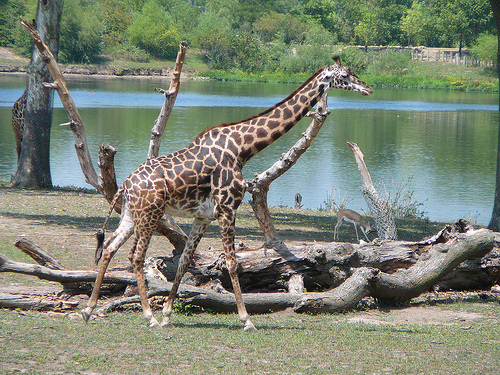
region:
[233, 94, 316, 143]
neck of the giraffe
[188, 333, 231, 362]
grass on the ground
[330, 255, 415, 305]
log on the ground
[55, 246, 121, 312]
back leg of the animal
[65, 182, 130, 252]
tail of the giraffe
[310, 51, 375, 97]
head of the giraffe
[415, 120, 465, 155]
water next to giraffes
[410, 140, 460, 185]
light and dark water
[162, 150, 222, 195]
brown spots on the animal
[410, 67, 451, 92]
grass in the distance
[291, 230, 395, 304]
logs on the ground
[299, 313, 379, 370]
grass on the ground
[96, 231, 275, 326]
legs of the giraffe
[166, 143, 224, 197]
brown spots on animal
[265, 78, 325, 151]
neck of the giraffe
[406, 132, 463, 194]
reflection in the water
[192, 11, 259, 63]
trees in the distance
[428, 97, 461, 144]
water next to giraffe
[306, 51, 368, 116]
head of the animal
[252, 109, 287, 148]
part of a neck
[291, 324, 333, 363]
part of a ground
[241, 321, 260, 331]
part of a hoof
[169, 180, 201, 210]
part of a tomach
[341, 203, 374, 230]
part of a deer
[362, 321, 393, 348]
part of a ground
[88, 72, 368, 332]
Giraffe walking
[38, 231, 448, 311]
Tree limbs laying on ground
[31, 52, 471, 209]
Lake surrounded by trees and shrubs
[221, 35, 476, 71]
Wooden bridge partially hidden behind shrubs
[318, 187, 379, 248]
Young animal bending down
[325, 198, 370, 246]
Fawn bending down eating grass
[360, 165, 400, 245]
Fencing around a tree limb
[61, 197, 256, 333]
Giraffe in mid-stride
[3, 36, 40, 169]
A giraffe partially hidden behind tree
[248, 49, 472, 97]
Yellow flowers on opposite side of lake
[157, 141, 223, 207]
brown and white animal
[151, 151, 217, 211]
brown spots on giraffe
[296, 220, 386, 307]
logs next to giraffe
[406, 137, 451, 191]
water in the background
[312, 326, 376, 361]
green and brown ground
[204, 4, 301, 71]
trees in the distance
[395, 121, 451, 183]
reflection in the water